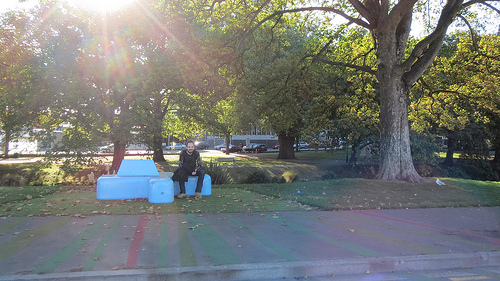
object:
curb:
[9, 249, 499, 279]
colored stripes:
[89, 216, 236, 266]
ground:
[2, 182, 500, 277]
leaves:
[347, 227, 356, 233]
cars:
[291, 141, 311, 149]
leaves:
[71, 199, 81, 203]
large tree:
[210, 0, 499, 184]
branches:
[210, 54, 259, 81]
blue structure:
[95, 155, 215, 202]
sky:
[303, 0, 500, 37]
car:
[243, 143, 269, 154]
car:
[194, 141, 211, 150]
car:
[220, 145, 241, 153]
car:
[98, 142, 116, 153]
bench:
[92, 155, 216, 202]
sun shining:
[66, 0, 217, 85]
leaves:
[483, 120, 486, 124]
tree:
[212, 15, 349, 160]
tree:
[1, 0, 195, 180]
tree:
[118, 0, 246, 167]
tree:
[406, 32, 499, 167]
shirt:
[177, 149, 205, 175]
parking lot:
[130, 139, 260, 157]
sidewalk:
[2, 204, 498, 278]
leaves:
[346, 130, 360, 140]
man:
[172, 140, 205, 200]